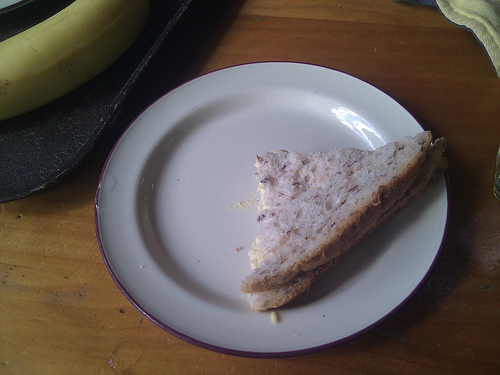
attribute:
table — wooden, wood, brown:
[2, 1, 498, 374]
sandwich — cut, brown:
[248, 131, 447, 310]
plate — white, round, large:
[92, 59, 449, 360]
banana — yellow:
[3, 3, 158, 122]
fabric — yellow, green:
[437, 2, 500, 64]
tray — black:
[1, 2, 192, 205]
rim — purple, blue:
[252, 48, 364, 93]